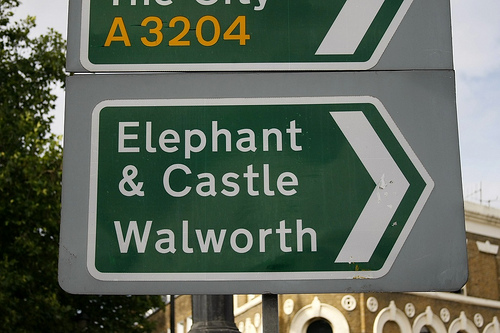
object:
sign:
[57, 71, 470, 298]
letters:
[117, 120, 144, 154]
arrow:
[328, 109, 411, 263]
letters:
[102, 14, 133, 47]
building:
[131, 199, 500, 332]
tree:
[0, 1, 166, 332]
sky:
[3, 1, 500, 208]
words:
[112, 219, 317, 255]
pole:
[182, 293, 240, 332]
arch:
[285, 297, 349, 332]